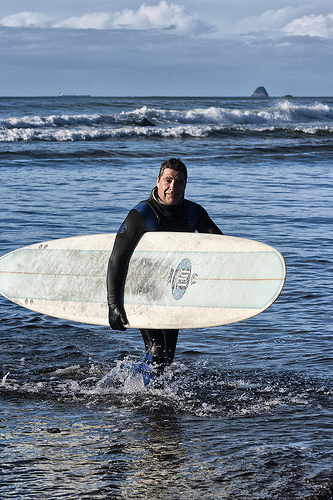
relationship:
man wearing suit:
[107, 159, 225, 383] [106, 189, 224, 385]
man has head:
[107, 159, 225, 383] [155, 158, 189, 205]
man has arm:
[107, 159, 225, 383] [106, 199, 141, 332]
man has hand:
[107, 159, 225, 383] [109, 304, 130, 331]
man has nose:
[107, 159, 225, 383] [169, 182, 176, 194]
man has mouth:
[107, 159, 225, 383] [165, 191, 180, 197]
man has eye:
[107, 159, 225, 383] [165, 178, 173, 183]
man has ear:
[107, 159, 225, 383] [155, 173, 160, 186]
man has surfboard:
[107, 159, 225, 383] [3, 232, 285, 329]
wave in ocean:
[1, 100, 333, 144] [1, 95, 333, 499]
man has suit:
[107, 159, 225, 383] [106, 189, 224, 385]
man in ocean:
[107, 159, 225, 383] [1, 95, 333, 499]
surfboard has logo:
[3, 232, 285, 329] [173, 258, 191, 301]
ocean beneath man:
[1, 95, 333, 499] [107, 159, 225, 383]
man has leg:
[107, 159, 225, 383] [139, 327, 166, 368]